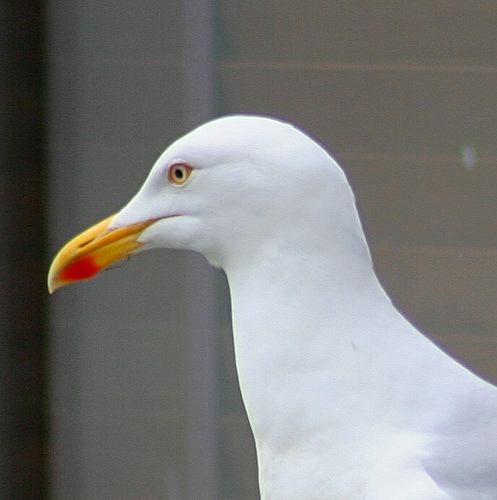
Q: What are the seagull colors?
A: The seagull is white, and orange.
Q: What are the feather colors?
A: The feathers are white.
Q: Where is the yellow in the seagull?
A: The eye on the seagull is yellow.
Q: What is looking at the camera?
A: The seagull is looking at the camera.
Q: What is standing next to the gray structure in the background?
A: The white seagull.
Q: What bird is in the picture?
A: A seagull.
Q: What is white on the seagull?
A: Feathers.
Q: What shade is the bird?
A: White.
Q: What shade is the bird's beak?
A: Yellow.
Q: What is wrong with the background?
A: Very blurry.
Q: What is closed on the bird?
A: Beak.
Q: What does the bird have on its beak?
A: Red spot.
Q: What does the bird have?
A: A long neck.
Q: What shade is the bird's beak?
A: Mostly orange.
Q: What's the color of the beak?
A: Yellow.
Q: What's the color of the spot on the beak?
A: Red.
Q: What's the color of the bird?
A: White.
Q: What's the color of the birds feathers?
A: White.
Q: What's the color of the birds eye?
A: Yellow.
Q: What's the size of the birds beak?
A: Large.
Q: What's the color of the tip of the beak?
A: Light yellow.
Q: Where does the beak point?
A: Down.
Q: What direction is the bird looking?
A: Left.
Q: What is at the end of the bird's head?
A: A yellow beak.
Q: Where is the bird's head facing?
A: To the left.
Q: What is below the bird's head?
A: A white neck.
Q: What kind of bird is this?
A: A seagull.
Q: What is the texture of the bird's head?
A: Smooth.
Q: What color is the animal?
A: White.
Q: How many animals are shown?
A: One.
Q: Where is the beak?
A: On bird.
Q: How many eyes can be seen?
A: One.